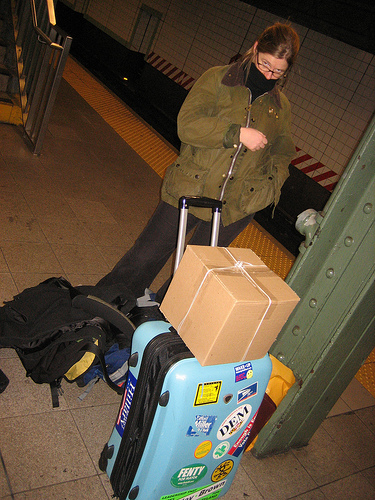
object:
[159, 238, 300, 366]
box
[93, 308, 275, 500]
luggage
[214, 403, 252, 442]
stickers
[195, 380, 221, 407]
stickers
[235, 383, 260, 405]
stickers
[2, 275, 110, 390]
bags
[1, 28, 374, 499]
ground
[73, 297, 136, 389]
bags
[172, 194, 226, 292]
handle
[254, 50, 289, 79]
glasses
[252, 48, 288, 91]
face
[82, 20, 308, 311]
woman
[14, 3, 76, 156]
handrail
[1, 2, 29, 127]
stairs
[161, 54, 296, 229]
jacket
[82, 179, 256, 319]
pants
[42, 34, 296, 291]
area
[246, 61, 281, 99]
collar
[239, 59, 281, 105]
turtleneck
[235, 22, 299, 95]
hair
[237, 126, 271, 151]
hand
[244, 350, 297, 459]
envelope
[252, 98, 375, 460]
beam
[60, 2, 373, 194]
wall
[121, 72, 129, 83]
light